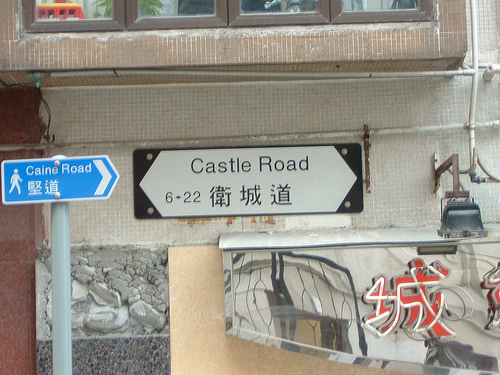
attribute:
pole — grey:
[47, 201, 74, 373]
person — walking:
[9, 167, 22, 194]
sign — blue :
[0, 157, 120, 200]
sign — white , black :
[133, 141, 363, 221]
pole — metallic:
[45, 196, 75, 374]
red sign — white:
[361, 255, 453, 337]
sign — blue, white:
[2, 152, 122, 206]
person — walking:
[5, 165, 25, 195]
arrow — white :
[81, 154, 121, 214]